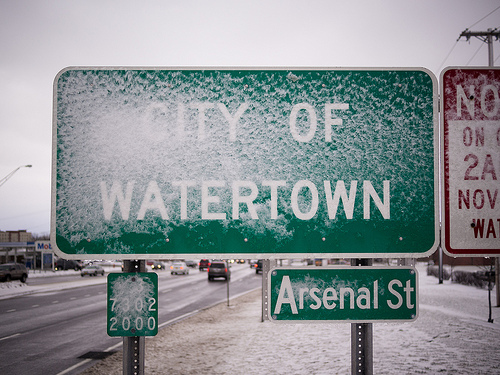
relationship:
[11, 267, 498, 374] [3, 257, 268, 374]
ground on road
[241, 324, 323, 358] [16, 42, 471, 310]
snow on sign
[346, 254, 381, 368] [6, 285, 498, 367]
post on ground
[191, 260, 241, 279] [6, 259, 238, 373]
car on road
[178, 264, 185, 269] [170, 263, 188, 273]
tail light on car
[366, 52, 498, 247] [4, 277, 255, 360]
sign by road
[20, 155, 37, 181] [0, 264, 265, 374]
light over road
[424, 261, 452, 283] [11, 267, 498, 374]
bush on ground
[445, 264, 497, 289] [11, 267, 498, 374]
bush on ground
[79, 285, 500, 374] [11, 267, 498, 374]
snow covers ground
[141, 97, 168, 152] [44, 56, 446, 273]
letter on sign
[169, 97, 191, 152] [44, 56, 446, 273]
letter on sign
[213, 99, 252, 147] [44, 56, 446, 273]
letter on sign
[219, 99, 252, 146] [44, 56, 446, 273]
letter on sign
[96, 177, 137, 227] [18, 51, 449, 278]
letter on sign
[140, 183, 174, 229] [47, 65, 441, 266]
letter a on sign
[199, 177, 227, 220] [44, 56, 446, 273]
letter e on sign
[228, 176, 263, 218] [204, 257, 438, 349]
letter r on sign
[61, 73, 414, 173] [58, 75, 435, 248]
snow on sign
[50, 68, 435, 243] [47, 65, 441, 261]
snow on sign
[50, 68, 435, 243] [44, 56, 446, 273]
snow on sign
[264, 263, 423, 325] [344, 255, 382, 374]
sign on pole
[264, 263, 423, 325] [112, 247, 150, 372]
sign on pole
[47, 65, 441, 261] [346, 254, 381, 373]
sign on post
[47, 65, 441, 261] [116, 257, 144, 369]
sign on pole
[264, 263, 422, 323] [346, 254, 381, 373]
sign on post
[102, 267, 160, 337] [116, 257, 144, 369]
sign on pole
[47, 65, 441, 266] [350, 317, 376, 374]
sign on pole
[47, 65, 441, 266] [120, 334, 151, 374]
sign on pole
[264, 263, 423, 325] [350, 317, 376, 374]
sign on pole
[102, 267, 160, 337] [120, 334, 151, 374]
sign on pole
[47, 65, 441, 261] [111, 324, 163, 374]
sign on poles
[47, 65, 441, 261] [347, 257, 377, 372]
sign on pole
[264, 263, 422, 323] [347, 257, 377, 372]
sign on pole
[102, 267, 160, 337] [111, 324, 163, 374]
sign on poles